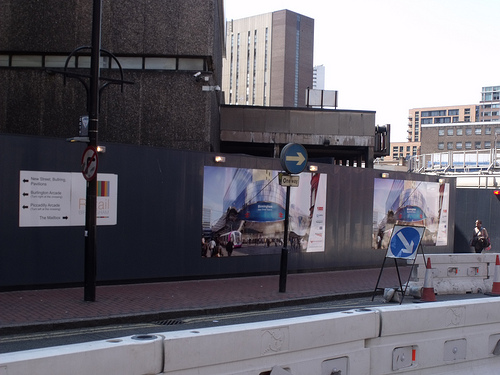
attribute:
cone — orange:
[402, 250, 494, 374]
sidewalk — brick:
[1, 262, 418, 339]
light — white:
[215, 150, 227, 164]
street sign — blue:
[387, 224, 432, 261]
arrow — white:
[397, 229, 416, 254]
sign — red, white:
[75, 146, 106, 181]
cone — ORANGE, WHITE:
[417, 248, 435, 305]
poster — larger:
[368, 174, 451, 253]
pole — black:
[270, 184, 295, 296]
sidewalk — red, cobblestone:
[1, 254, 497, 334]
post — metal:
[78, 2, 105, 303]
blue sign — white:
[283, 141, 308, 173]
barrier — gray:
[1, 134, 454, 291]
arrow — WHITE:
[280, 144, 306, 167]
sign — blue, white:
[281, 138, 308, 173]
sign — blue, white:
[283, 142, 308, 173]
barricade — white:
[91, 292, 491, 373]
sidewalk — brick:
[7, 245, 485, 322]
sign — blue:
[384, 225, 427, 262]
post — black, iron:
[275, 182, 295, 294]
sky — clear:
[325, 0, 483, 100]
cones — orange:
[420, 256, 437, 303]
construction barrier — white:
[22, 290, 498, 371]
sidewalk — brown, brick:
[122, 249, 422, 309]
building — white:
[312, 62, 327, 91]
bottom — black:
[72, 223, 102, 303]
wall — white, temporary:
[116, 152, 186, 282]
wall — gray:
[2, 130, 455, 286]